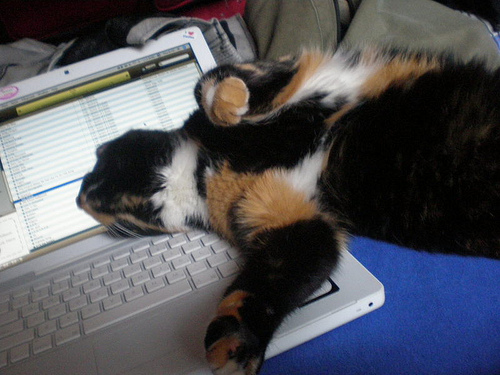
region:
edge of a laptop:
[363, 297, 377, 313]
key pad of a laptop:
[100, 250, 158, 292]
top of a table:
[426, 322, 450, 347]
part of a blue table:
[358, 349, 387, 353]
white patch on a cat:
[301, 165, 312, 177]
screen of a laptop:
[83, 98, 93, 105]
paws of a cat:
[231, 307, 264, 343]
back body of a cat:
[416, 176, 443, 226]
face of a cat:
[82, 164, 129, 203]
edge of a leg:
[279, 251, 302, 291]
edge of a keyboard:
[297, 297, 348, 355]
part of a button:
[86, 292, 129, 344]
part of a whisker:
[113, 216, 138, 235]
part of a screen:
[33, 207, 76, 260]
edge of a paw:
[197, 327, 237, 367]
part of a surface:
[413, 275, 472, 335]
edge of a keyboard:
[326, 317, 363, 334]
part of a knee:
[309, 212, 350, 278]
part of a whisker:
[105, 215, 139, 252]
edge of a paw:
[208, 322, 241, 359]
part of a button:
[125, 290, 180, 334]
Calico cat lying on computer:
[76, 41, 498, 373]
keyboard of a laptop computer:
[1, 221, 256, 373]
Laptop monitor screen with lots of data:
[2, 43, 204, 259]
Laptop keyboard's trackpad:
[90, 282, 227, 371]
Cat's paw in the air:
[192, 57, 288, 131]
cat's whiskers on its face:
[90, 208, 165, 248]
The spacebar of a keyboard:
[80, 273, 194, 334]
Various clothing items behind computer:
[3, 4, 498, 89]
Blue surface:
[258, 230, 497, 373]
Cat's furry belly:
[322, 47, 499, 263]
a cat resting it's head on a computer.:
[63, 115, 203, 276]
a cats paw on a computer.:
[206, 296, 318, 370]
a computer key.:
[185, 268, 220, 298]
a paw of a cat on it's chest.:
[182, 53, 259, 146]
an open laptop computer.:
[0, 21, 389, 372]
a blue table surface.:
[255, 232, 497, 374]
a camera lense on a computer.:
[58, 56, 76, 86]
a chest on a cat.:
[175, 103, 356, 196]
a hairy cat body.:
[270, 61, 498, 254]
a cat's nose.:
[73, 177, 100, 232]